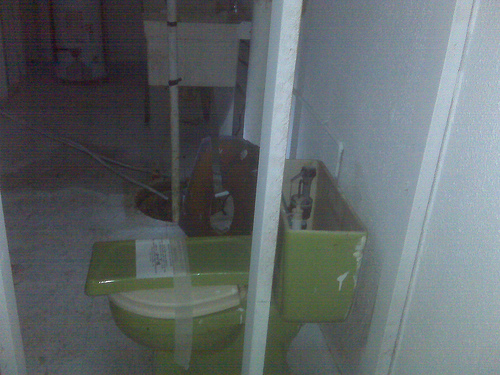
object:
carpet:
[20, 177, 87, 260]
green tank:
[263, 147, 365, 321]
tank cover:
[274, 157, 363, 337]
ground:
[440, 126, 468, 155]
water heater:
[50, 1, 105, 80]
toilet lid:
[83, 227, 277, 296]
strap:
[162, 218, 196, 373]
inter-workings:
[285, 162, 316, 229]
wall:
[164, 107, 269, 206]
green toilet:
[81, 153, 372, 374]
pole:
[167, 48, 180, 229]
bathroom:
[0, 0, 495, 372]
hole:
[128, 163, 198, 234]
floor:
[6, 55, 358, 375]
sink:
[137, 15, 243, 87]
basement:
[0, 0, 494, 372]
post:
[236, 0, 305, 375]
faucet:
[226, 0, 243, 17]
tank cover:
[83, 230, 255, 298]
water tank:
[41, 0, 112, 82]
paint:
[346, 237, 373, 293]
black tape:
[161, 17, 180, 30]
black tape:
[164, 75, 186, 87]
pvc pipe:
[163, 0, 184, 227]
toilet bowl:
[110, 284, 255, 375]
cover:
[113, 287, 236, 320]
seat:
[110, 284, 242, 315]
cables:
[4, 93, 135, 177]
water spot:
[4, 137, 166, 213]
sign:
[130, 234, 180, 275]